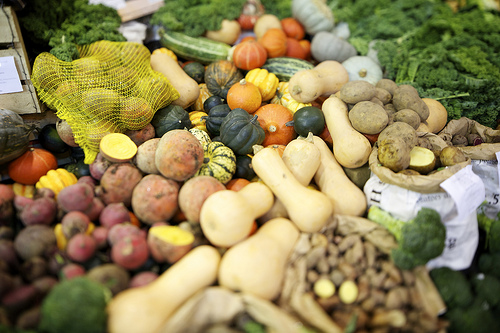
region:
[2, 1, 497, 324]
Assortment of vegetables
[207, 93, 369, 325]
Several squash in the middle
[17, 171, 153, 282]
A bunch of potatoes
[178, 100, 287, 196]
Decorative pumpkins in the middle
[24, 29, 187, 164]
A bag of potatoes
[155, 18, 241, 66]
A single zucchini near the back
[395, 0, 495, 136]
Leafy vegetable in the corner right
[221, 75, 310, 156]
Two oranges in the middle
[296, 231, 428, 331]
A mix of small legumes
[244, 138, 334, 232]
squash on a table of vegetables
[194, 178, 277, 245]
squash on a table of vegetables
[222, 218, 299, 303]
squash on a table of vegetables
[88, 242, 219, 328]
squash on a table of vegetables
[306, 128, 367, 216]
squash on a table of vegetables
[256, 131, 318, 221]
squash on a table of vegetables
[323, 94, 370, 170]
squash on a table of vegetables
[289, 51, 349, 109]
squash on a table of vegetables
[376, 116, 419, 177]
potato on a table of vegetables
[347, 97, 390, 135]
potato on a table of vegetables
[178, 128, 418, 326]
a group of vegetables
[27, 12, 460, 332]
a mixed view of vegetables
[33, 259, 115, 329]
a part of green leafs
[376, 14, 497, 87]
green veges on the side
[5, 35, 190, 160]
a nut in the top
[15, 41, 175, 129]
a apples packed with nut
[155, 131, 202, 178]
vegetable in big pile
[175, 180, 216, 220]
vegetable in big pile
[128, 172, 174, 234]
vegetable in big pile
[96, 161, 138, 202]
vegetable in big pile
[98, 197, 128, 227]
vegetable in big pile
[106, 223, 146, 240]
vegetable in big pile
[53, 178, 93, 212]
vegetable in big pile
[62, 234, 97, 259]
vegetable in big pile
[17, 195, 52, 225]
vegetable in big pile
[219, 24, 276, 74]
The goard is orange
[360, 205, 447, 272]
The broccoli is green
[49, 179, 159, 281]
The veggies are round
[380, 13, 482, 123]
The veggies are green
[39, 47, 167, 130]
The food is in a bag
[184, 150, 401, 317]
The squash are light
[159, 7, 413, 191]
Everything is in a pile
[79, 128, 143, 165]
The food is cut